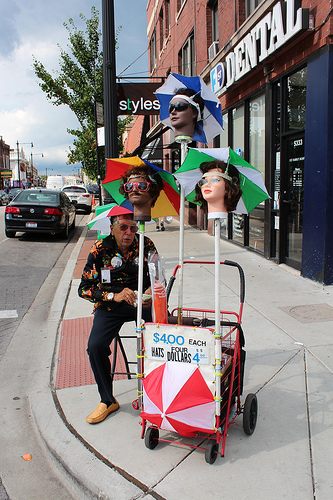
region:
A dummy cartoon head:
[187, 149, 254, 227]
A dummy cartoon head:
[150, 62, 238, 141]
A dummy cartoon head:
[92, 195, 143, 253]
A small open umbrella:
[136, 359, 218, 434]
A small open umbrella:
[181, 140, 278, 202]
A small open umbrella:
[151, 71, 239, 164]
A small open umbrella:
[103, 153, 183, 219]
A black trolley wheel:
[237, 394, 268, 430]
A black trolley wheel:
[195, 436, 222, 471]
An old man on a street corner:
[78, 206, 167, 425]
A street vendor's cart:
[138, 96, 274, 465]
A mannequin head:
[122, 164, 163, 222]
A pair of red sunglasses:
[121, 179, 153, 193]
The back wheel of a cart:
[243, 392, 258, 435]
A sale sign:
[149, 328, 212, 365]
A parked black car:
[4, 189, 78, 237]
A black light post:
[100, 0, 119, 212]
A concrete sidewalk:
[32, 196, 331, 498]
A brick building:
[145, 1, 331, 285]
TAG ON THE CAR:
[27, 223, 34, 227]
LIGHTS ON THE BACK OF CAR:
[42, 206, 62, 214]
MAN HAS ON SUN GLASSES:
[117, 225, 137, 233]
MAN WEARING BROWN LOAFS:
[91, 406, 102, 420]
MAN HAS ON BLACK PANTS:
[96, 337, 100, 350]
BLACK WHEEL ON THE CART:
[246, 398, 254, 428]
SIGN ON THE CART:
[140, 323, 209, 358]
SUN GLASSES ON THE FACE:
[120, 178, 146, 196]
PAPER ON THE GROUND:
[21, 450, 42, 465]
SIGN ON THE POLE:
[120, 75, 159, 115]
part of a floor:
[255, 466, 268, 482]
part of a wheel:
[205, 435, 218, 444]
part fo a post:
[217, 417, 237, 454]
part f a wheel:
[247, 417, 250, 426]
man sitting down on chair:
[78, 203, 178, 426]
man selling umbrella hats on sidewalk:
[78, 70, 263, 464]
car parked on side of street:
[4, 185, 78, 239]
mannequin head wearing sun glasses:
[166, 86, 201, 144]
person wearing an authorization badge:
[78, 203, 162, 313]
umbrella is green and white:
[172, 142, 266, 223]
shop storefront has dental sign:
[198, 0, 316, 275]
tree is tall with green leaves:
[31, 5, 117, 224]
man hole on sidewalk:
[277, 295, 331, 336]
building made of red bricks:
[145, 5, 327, 275]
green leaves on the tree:
[71, 93, 97, 113]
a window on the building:
[282, 134, 311, 214]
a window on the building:
[268, 73, 323, 143]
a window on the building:
[250, 106, 268, 225]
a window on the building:
[236, 109, 244, 160]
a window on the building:
[205, 123, 219, 217]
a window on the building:
[205, 6, 213, 43]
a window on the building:
[186, 36, 199, 75]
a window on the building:
[154, 15, 181, 49]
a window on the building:
[274, 87, 300, 155]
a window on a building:
[146, 37, 155, 70]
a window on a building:
[284, 76, 306, 125]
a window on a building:
[279, 134, 303, 268]